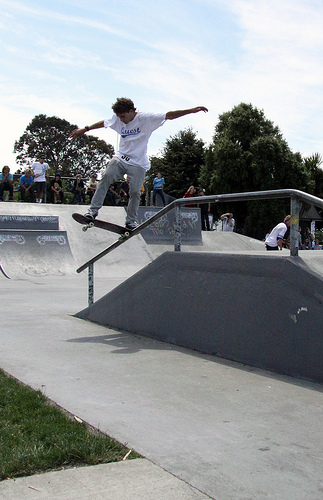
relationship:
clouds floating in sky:
[236, 2, 313, 46] [1, 1, 310, 95]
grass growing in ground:
[0, 366, 145, 478] [0, 414, 78, 475]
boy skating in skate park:
[70, 96, 208, 226] [1, 203, 311, 434]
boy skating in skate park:
[70, 96, 208, 226] [2, 188, 310, 398]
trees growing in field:
[207, 101, 312, 190] [0, 418, 85, 469]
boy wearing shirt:
[70, 96, 208, 226] [103, 113, 164, 169]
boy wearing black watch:
[70, 96, 208, 226] [79, 119, 97, 139]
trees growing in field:
[207, 101, 312, 190] [1, 396, 50, 467]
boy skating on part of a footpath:
[70, 96, 208, 226] [2, 287, 323, 480]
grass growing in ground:
[0, 392, 56, 470] [0, 401, 50, 470]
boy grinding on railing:
[70, 96, 208, 226] [172, 186, 300, 208]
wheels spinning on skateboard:
[82, 221, 96, 230] [71, 212, 137, 239]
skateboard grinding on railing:
[72, 211, 134, 238] [173, 187, 303, 218]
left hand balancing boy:
[142, 100, 217, 129] [70, 96, 208, 226]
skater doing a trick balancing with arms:
[29, 74, 211, 234] [71, 104, 209, 134]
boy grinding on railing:
[70, 96, 208, 226] [171, 188, 304, 249]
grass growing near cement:
[0, 366, 145, 478] [135, 361, 302, 498]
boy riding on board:
[70, 96, 208, 226] [72, 213, 139, 238]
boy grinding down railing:
[70, 99, 208, 229] [77, 186, 317, 302]